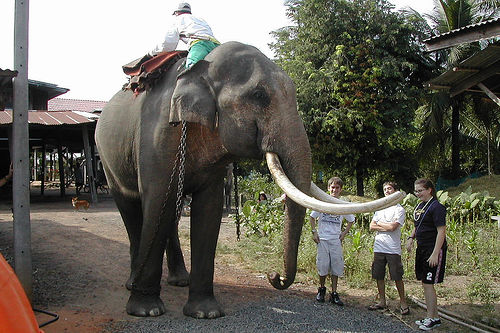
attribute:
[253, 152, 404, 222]
tusks — long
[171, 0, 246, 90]
man — riding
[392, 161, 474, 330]
girl — wearing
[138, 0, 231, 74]
person — wearing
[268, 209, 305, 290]
trunk — long, shaped like J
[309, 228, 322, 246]
right hand — wearing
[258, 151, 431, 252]
tusks — long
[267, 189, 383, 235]
tusks — white, long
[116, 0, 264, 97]
man — riding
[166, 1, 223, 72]
pants — green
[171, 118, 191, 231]
chain — attached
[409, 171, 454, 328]
girl — smiling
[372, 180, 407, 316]
boy — wearing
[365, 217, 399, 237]
arms — tucked